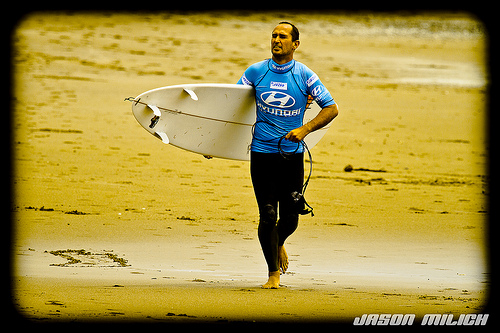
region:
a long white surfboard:
[129, 83, 328, 165]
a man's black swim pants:
[243, 151, 303, 273]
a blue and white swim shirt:
[230, 52, 331, 153]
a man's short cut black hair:
[273, 20, 299, 45]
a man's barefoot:
[273, 245, 291, 275]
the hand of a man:
[285, 122, 305, 142]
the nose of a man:
[271, 32, 277, 43]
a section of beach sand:
[335, 82, 490, 177]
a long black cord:
[272, 128, 312, 190]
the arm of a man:
[297, 69, 339, 129]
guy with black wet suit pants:
[241, 151, 314, 263]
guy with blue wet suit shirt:
[251, 55, 317, 163]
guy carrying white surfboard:
[188, 114, 217, 152]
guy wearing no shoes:
[260, 264, 322, 306]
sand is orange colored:
[365, 190, 409, 250]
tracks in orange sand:
[351, 150, 423, 216]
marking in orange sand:
[47, 233, 149, 287]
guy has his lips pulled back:
[263, 38, 309, 73]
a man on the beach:
[152, 48, 452, 320]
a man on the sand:
[219, 68, 396, 323]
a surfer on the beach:
[214, 46, 376, 262]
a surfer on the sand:
[201, 43, 351, 323]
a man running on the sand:
[208, 55, 361, 317]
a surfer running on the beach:
[160, 48, 310, 318]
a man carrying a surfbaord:
[85, 46, 496, 198]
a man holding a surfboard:
[162, 20, 495, 280]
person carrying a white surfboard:
[111, 15, 337, 294]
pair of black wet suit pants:
[244, 149, 313, 279]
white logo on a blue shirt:
[252, 88, 302, 112]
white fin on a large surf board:
[180, 85, 200, 104]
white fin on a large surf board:
[143, 99, 161, 118]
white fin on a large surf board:
[154, 128, 173, 146]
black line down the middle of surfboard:
[134, 99, 256, 132]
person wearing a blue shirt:
[117, 18, 348, 292]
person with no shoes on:
[117, 18, 350, 296]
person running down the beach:
[113, 15, 354, 296]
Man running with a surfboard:
[130, 20, 341, 290]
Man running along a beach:
[200, 17, 340, 289]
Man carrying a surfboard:
[132, 18, 338, 289]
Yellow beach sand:
[13, 11, 486, 322]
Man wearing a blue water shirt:
[201, 19, 339, 289]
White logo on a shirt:
[259, 88, 296, 110]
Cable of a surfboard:
[250, 115, 317, 217]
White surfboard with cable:
[130, 79, 338, 219]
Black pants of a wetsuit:
[245, 142, 307, 293]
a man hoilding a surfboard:
[111, 30, 341, 308]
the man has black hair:
[123, 23, 338, 298]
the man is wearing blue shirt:
[118, 15, 345, 303]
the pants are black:
[248, 145, 323, 295]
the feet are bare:
[250, 240, 299, 296]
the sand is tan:
[56, 188, 230, 312]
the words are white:
[345, 303, 492, 330]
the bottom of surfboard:
[134, 89, 249, 153]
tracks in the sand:
[46, 235, 122, 282]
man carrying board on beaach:
[240, 15, 314, 293]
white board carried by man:
[133, 59, 242, 169]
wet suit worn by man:
[246, 156, 319, 277]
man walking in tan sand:
[254, 243, 294, 293]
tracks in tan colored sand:
[140, 192, 177, 222]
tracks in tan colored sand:
[338, 150, 388, 192]